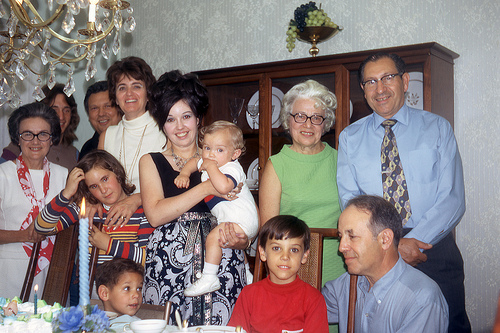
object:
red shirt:
[228, 275, 329, 332]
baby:
[173, 120, 260, 297]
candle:
[65, 196, 100, 308]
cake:
[1, 281, 136, 333]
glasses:
[285, 106, 330, 125]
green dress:
[265, 143, 349, 332]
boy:
[226, 214, 330, 332]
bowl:
[293, 22, 340, 54]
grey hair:
[280, 76, 339, 135]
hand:
[196, 160, 220, 172]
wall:
[0, 4, 498, 327]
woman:
[138, 68, 250, 330]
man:
[319, 197, 452, 333]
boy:
[96, 256, 142, 314]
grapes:
[279, 1, 341, 53]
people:
[0, 54, 472, 331]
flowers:
[49, 300, 114, 330]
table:
[0, 295, 191, 333]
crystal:
[121, 13, 137, 33]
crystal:
[97, 41, 111, 60]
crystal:
[83, 59, 99, 81]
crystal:
[59, 75, 75, 96]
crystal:
[15, 60, 27, 80]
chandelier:
[0, 1, 135, 107]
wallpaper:
[2, 2, 495, 332]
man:
[335, 49, 470, 329]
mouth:
[208, 158, 218, 165]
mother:
[140, 70, 252, 326]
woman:
[255, 79, 340, 285]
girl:
[33, 150, 155, 298]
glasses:
[360, 73, 398, 87]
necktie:
[378, 120, 412, 224]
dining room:
[0, 2, 500, 329]